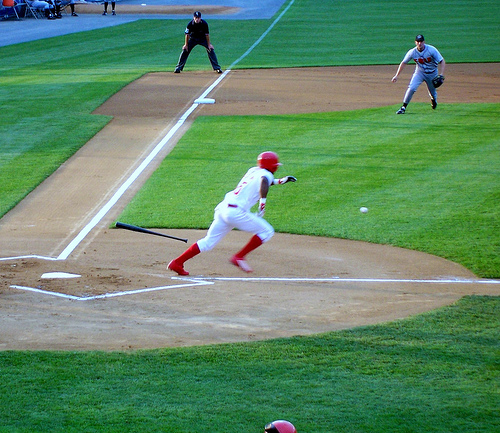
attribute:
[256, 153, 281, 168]
helmet — red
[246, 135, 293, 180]
helmet — red, shiny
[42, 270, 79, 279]
base — white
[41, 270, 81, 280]
home plate — white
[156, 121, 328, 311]
man — playing baseball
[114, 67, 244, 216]
lines — white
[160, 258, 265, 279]
shoes — red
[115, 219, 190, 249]
baseball bat — black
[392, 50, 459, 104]
uniform — gray and red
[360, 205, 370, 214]
baseball — round, white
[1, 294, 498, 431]
grass — green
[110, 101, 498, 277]
grass — green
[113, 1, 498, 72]
grass — green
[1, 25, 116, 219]
grass — green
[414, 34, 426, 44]
hat — blue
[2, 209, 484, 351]
section — dirt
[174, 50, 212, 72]
shirt — black